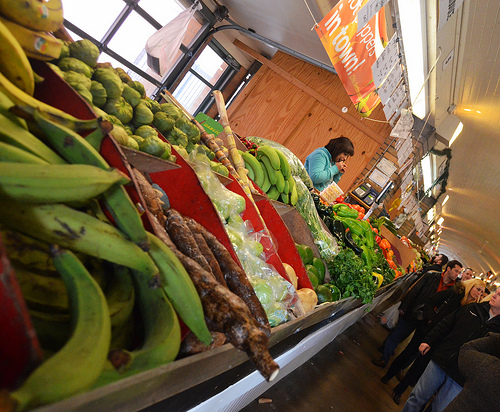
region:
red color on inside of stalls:
[111, 142, 321, 354]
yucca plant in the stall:
[150, 187, 289, 382]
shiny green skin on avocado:
[303, 250, 338, 287]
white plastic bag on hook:
[144, 4, 228, 110]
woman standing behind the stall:
[299, 115, 381, 201]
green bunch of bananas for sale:
[236, 142, 298, 207]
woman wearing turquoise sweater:
[301, 150, 336, 199]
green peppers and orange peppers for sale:
[329, 198, 401, 281]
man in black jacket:
[394, 270, 466, 330]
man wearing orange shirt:
[429, 274, 454, 304]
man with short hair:
[443, 257, 466, 268]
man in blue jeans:
[403, 358, 463, 405]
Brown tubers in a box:
[138, 166, 278, 380]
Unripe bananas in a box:
[242, 143, 301, 205]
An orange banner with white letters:
[312, 2, 395, 117]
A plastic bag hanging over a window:
[145, 2, 197, 74]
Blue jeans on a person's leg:
[402, 359, 459, 410]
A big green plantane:
[6, 240, 112, 410]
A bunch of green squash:
[60, 38, 165, 159]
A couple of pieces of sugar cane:
[210, 88, 251, 196]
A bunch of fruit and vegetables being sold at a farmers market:
[0, 3, 409, 410]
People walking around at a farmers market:
[370, 253, 498, 410]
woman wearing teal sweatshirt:
[294, 115, 355, 205]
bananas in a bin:
[239, 134, 297, 201]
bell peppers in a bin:
[367, 222, 407, 279]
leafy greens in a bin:
[328, 240, 380, 300]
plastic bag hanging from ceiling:
[150, 3, 199, 73]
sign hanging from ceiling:
[320, 5, 409, 108]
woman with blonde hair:
[450, 269, 482, 310]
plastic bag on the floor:
[379, 295, 402, 332]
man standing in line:
[442, 275, 494, 357]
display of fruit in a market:
[1, 2, 426, 389]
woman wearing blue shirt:
[309, 132, 352, 188]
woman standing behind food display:
[303, 112, 356, 222]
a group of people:
[381, 232, 494, 409]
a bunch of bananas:
[6, 5, 203, 405]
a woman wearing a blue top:
[308, 141, 345, 206]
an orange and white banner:
[313, 6, 400, 124]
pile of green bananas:
[239, 128, 302, 210]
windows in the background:
[54, 5, 251, 127]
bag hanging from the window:
[144, 0, 216, 92]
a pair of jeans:
[409, 343, 459, 410]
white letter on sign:
[323, 3, 343, 26]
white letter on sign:
[325, 14, 342, 37]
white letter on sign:
[331, 25, 349, 45]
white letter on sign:
[334, 34, 350, 54]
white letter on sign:
[336, 41, 353, 65]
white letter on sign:
[344, 53, 356, 69]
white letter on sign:
[366, 36, 378, 48]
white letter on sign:
[358, 30, 371, 46]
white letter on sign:
[355, 22, 372, 39]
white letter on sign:
[351, 0, 362, 14]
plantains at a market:
[3, 100, 216, 401]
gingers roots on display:
[124, 160, 288, 387]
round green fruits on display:
[66, 28, 173, 153]